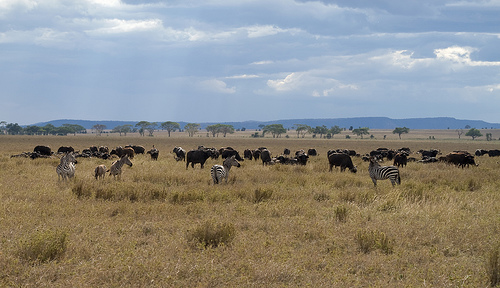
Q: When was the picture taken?
A: Daytime.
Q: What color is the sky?
A: Blue.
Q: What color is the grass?
A: Brown.